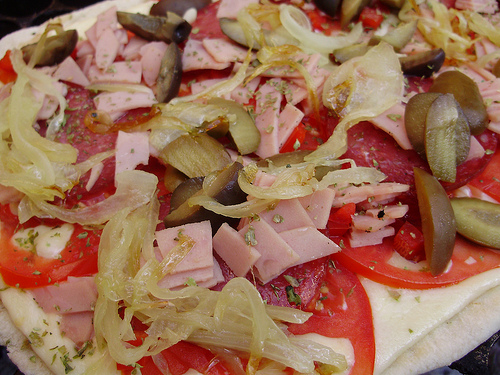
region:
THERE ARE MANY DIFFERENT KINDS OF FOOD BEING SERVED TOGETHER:
[2, 2, 497, 372]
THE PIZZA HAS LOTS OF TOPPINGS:
[0, 1, 496, 372]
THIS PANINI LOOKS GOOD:
[0, 0, 499, 373]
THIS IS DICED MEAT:
[210, 185, 350, 286]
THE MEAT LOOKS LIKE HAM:
[208, 177, 338, 287]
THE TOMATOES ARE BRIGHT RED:
[80, 242, 345, 363]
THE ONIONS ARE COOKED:
[96, 261, 371, 371]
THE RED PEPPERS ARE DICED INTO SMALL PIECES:
[387, 210, 423, 263]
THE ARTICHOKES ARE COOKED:
[410, 152, 465, 279]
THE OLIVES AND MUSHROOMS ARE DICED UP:
[113, 2, 202, 107]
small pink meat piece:
[208, 221, 254, 276]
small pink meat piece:
[236, 217, 296, 282]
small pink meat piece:
[278, 224, 345, 271]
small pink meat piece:
[258, 194, 315, 235]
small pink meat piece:
[303, 182, 333, 228]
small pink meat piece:
[156, 224, 217, 268]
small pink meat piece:
[141, 243, 213, 285]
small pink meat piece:
[41, 282, 103, 319]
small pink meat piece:
[111, 125, 148, 172]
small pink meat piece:
[254, 78, 277, 163]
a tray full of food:
[26, 12, 465, 370]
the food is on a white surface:
[358, 264, 477, 373]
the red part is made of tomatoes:
[346, 228, 391, 371]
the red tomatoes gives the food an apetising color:
[257, 201, 432, 373]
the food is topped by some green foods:
[191, 63, 396, 336]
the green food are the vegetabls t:
[130, 35, 408, 322]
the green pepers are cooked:
[398, 36, 498, 250]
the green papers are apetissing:
[387, 81, 498, 258]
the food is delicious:
[30, 82, 216, 272]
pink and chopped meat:
[50, 18, 346, 290]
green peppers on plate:
[390, 85, 480, 279]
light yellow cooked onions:
[94, 215, 270, 367]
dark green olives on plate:
[40, 31, 187, 85]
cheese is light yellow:
[356, 273, 484, 371]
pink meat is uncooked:
[76, 45, 356, 297]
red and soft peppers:
[331, 205, 441, 363]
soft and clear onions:
[115, 217, 318, 358]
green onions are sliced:
[102, 103, 271, 222]